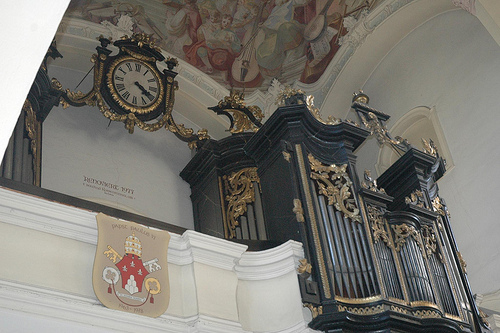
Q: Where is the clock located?
A: Near the ceiling.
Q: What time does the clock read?
A: 4:20.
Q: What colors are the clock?
A: Black and gold.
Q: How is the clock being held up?
A: It is attached to the mantle.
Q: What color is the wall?
A: White.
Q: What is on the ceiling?
A: A painting.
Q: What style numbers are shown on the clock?
A: Roman numerals.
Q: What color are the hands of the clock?
A: Black.